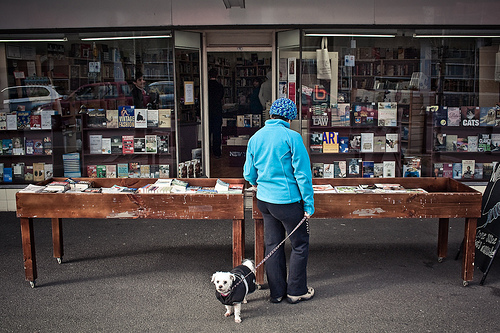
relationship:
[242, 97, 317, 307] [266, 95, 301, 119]
person wearing blue hat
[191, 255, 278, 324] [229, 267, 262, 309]
dog wearing a coat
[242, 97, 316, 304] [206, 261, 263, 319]
person walking her dog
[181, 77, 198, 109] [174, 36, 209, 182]
sign on door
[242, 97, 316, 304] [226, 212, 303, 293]
person holding leash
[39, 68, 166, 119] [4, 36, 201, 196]
reflection in window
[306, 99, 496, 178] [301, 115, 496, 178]
books on a shelf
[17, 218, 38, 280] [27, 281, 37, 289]
leg on a wheel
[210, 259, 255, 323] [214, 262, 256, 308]
dog wearing a vest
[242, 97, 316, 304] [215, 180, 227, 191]
person looking at books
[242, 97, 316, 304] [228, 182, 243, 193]
person looking at books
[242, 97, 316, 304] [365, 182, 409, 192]
person looking at books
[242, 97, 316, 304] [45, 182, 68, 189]
person looking at books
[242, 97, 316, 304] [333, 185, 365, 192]
person looking at books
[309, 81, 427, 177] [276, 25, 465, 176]
books in window